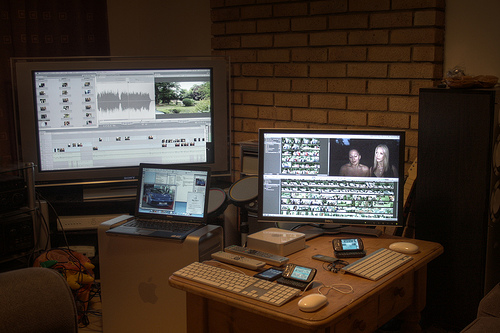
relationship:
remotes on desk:
[199, 227, 313, 291] [164, 229, 450, 333]